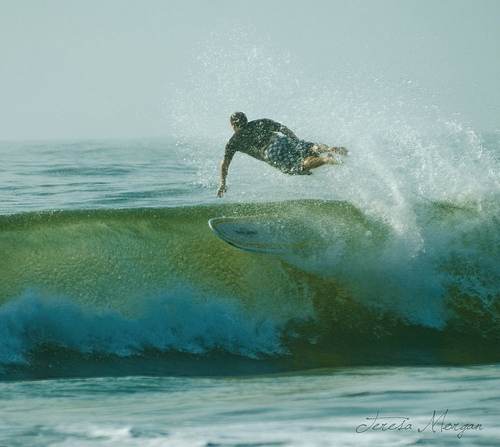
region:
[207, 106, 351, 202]
surfer is off his board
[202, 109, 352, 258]
the surfer is doing a stunt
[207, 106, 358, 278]
man is surfing in the ocean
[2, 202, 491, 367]
large wave heading to shore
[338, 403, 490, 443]
signature on the lower right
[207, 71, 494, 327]
large splash from the wave hitting the surfer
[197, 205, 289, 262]
partial view of the surfboard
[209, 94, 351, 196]
the man has fallen off his board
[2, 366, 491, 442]
seafoam headed to shore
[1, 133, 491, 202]
area of open ocean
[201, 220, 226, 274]
part of an ocean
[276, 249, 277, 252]
edge of a board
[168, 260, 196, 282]
part of an arm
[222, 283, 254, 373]
edge of a wave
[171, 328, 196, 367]
part of a cloud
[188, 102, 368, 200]
Guy hitting a big wave sideways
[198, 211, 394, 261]
A surfboard on a wave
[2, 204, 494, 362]
A big wave in the ocean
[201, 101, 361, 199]
The surfer has a helmet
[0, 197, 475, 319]
The wave is blue and green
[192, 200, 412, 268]
The surf board has yellow stripes on it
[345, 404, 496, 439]
The photographers name is imprinted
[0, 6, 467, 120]
The sky is gloomy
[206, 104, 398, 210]
The surfer has a black shirt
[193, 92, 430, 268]
The surfer hit the wave wrong and is falling off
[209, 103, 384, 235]
man is surfing on water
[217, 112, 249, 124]
man has dark hair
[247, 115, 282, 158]
man has black shirt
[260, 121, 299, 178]
blue and white shorts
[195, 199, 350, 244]
white and yellow board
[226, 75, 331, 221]
man is in air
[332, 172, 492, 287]
white wake behind board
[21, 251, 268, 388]
man behind white wave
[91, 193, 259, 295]
water is dark green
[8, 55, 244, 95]
grey and cloudy sky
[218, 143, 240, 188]
the arm of a surfer in the air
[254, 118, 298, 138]
the arm of a surfer in the air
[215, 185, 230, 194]
the hand of a surfer in the air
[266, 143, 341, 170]
the leg of a surfer in the air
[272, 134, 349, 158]
the leg of a surfer in the air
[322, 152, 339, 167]
the foot of a surfer in the air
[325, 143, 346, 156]
the foot of a surfer in the air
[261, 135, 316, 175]
the shorts of a surfer in the air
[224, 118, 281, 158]
the shirt of a surfer in the air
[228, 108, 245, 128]
the head of a surfer in the air